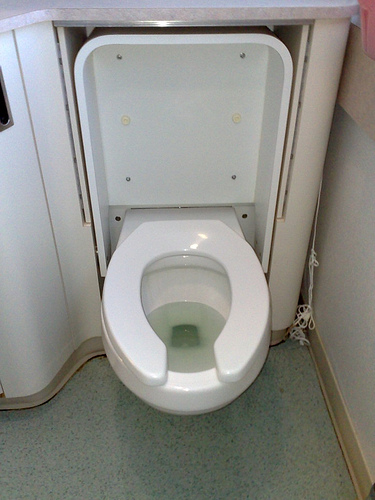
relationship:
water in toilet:
[145, 300, 225, 372] [97, 206, 271, 416]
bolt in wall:
[239, 53, 246, 59] [17, 14, 355, 361]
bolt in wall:
[115, 53, 124, 63] [17, 14, 355, 361]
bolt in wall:
[230, 175, 238, 182] [17, 14, 355, 361]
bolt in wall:
[124, 176, 132, 182] [17, 14, 355, 361]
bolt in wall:
[242, 212, 248, 221] [17, 14, 355, 361]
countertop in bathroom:
[1, 2, 361, 33] [1, 1, 375, 499]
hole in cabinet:
[2, 71, 16, 135] [3, 27, 75, 404]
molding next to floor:
[0, 295, 375, 499] [1, 329, 359, 500]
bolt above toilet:
[230, 175, 238, 182] [97, 206, 271, 416]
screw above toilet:
[231, 112, 243, 125] [97, 206, 271, 416]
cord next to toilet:
[284, 172, 320, 349] [97, 206, 271, 416]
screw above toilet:
[120, 115, 131, 127] [97, 206, 271, 416]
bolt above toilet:
[114, 214, 121, 222] [97, 206, 271, 416]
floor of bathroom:
[1, 329, 359, 500] [1, 1, 375, 499]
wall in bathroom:
[295, 98, 374, 483] [1, 1, 375, 499]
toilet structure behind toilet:
[72, 27, 297, 282] [97, 206, 271, 416]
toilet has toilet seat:
[97, 206, 271, 416] [101, 219, 265, 384]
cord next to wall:
[284, 172, 320, 349] [295, 98, 374, 483]